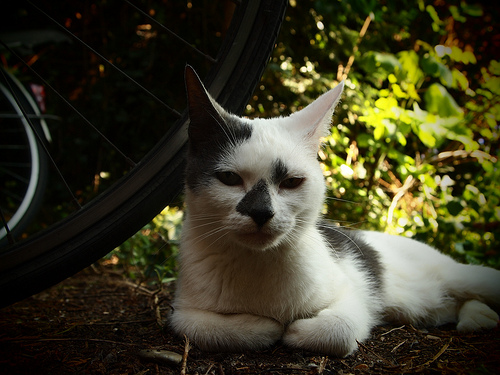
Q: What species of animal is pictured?
A: Feline.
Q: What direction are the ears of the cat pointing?
A: Upward.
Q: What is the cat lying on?
A: Dirt.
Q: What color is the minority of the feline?
A: Black.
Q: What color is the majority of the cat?
A: White.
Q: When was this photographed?
A: Daytime.